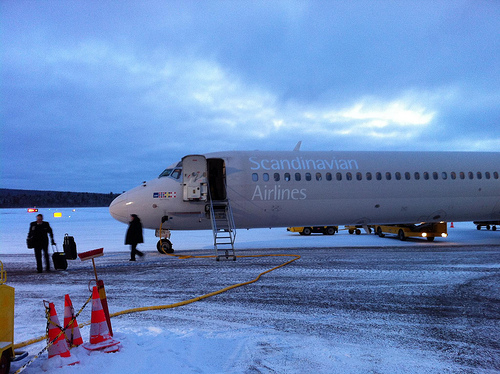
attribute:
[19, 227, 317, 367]
cord — yellow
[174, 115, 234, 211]
door — open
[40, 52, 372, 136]
clouds — white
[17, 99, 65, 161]
clouds — dark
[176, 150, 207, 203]
passenger door — opened